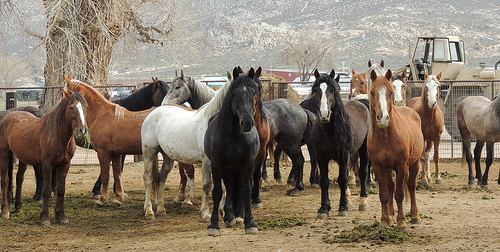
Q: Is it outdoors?
A: Yes, it is outdoors.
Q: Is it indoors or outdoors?
A: It is outdoors.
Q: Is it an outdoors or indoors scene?
A: It is outdoors.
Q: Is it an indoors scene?
A: No, it is outdoors.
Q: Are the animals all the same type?
A: Yes, all the animals are horses.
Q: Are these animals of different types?
A: No, all the animals are horses.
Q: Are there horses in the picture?
A: Yes, there is a horse.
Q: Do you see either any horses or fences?
A: Yes, there is a horse.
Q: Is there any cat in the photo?
A: No, there are no cats.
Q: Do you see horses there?
A: Yes, there is a horse.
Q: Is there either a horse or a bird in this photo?
A: Yes, there is a horse.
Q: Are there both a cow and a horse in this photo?
A: No, there is a horse but no cows.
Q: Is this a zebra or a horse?
A: This is a horse.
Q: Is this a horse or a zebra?
A: This is a horse.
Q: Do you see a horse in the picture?
A: Yes, there is a horse.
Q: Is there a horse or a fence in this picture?
A: Yes, there is a horse.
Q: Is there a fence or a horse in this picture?
A: Yes, there is a horse.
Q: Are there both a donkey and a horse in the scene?
A: No, there is a horse but no donkeys.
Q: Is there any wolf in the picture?
A: No, there are no wolves.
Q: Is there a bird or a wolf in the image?
A: No, there are no wolves or birds.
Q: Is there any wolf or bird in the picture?
A: No, there are no wolves or birds.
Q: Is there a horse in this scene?
A: Yes, there is a horse.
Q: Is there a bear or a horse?
A: Yes, there is a horse.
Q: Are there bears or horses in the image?
A: Yes, there is a horse.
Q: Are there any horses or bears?
A: Yes, there is a horse.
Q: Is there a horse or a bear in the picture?
A: Yes, there is a horse.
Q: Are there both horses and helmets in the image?
A: No, there is a horse but no helmets.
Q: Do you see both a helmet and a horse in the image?
A: No, there is a horse but no helmets.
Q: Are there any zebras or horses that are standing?
A: Yes, the horse is standing.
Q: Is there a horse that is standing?
A: Yes, there is a horse that is standing.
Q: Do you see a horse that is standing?
A: Yes, there is a horse that is standing.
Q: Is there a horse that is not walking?
A: Yes, there is a horse that is standing.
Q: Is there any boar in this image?
A: No, there are no boars.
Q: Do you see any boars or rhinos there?
A: No, there are no boars or rhinos.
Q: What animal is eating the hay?
A: The horse is eating the hay.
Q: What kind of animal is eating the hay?
A: The animal is a horse.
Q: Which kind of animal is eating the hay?
A: The animal is a horse.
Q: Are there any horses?
A: Yes, there is a horse.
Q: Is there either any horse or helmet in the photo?
A: Yes, there is a horse.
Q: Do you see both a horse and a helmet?
A: No, there is a horse but no helmets.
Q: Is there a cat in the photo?
A: No, there are no cats.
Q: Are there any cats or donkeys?
A: No, there are no cats or donkeys.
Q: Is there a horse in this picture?
A: Yes, there is a horse.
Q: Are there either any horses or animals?
A: Yes, there is a horse.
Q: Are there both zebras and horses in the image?
A: No, there is a horse but no zebras.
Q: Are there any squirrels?
A: No, there are no squirrels.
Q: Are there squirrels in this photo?
A: No, there are no squirrels.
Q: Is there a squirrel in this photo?
A: No, there are no squirrels.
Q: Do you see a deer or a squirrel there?
A: No, there are no squirrels or deer.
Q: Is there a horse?
A: Yes, there is a horse.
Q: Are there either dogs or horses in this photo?
A: Yes, there is a horse.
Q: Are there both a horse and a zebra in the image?
A: No, there is a horse but no zebras.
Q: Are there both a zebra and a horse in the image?
A: No, there is a horse but no zebras.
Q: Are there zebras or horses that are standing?
A: Yes, the horse is standing.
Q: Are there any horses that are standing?
A: Yes, there is a horse that is standing.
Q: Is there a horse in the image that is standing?
A: Yes, there is a horse that is standing.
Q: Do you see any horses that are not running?
A: Yes, there is a horse that is standing .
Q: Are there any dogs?
A: No, there are no dogs.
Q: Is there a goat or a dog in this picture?
A: No, there are no dogs or goats.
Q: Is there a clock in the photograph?
A: No, there are no clocks.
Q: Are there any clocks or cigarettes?
A: No, there are no clocks or cigarettes.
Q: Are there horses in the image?
A: Yes, there is a horse.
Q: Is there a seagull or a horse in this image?
A: Yes, there is a horse.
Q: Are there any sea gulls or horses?
A: Yes, there is a horse.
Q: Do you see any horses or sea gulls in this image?
A: Yes, there is a horse.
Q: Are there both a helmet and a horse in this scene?
A: No, there is a horse but no helmets.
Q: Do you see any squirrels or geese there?
A: No, there are no squirrels or geese.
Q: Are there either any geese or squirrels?
A: No, there are no squirrels or geese.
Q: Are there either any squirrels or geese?
A: No, there are no squirrels or geese.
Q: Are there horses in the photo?
A: Yes, there is a horse.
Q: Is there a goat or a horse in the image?
A: Yes, there is a horse.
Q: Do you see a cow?
A: No, there are no cows.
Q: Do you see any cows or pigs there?
A: No, there are no cows or pigs.